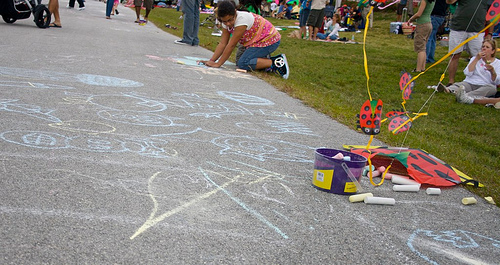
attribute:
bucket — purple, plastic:
[313, 147, 364, 193]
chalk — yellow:
[325, 151, 355, 167]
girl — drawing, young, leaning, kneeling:
[204, 1, 294, 81]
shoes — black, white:
[271, 51, 288, 77]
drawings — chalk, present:
[4, 38, 495, 263]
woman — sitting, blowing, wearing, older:
[437, 37, 497, 103]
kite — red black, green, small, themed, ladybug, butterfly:
[348, 90, 404, 136]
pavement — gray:
[1, 0, 497, 265]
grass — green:
[141, 2, 499, 206]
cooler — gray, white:
[388, 18, 411, 37]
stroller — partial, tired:
[6, 2, 51, 22]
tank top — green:
[410, 1, 437, 26]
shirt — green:
[414, 2, 444, 30]